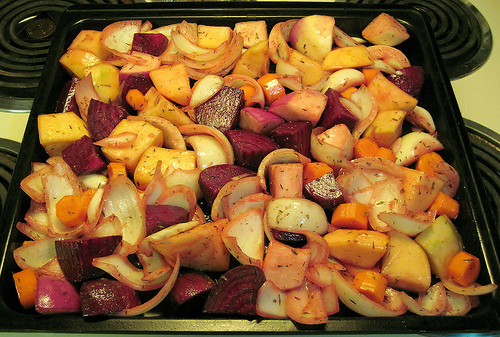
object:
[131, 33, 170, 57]
beet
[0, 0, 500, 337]
pan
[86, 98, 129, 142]
beet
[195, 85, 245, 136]
beet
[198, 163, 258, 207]
beet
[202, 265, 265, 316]
beet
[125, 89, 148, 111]
carrot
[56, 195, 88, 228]
carrot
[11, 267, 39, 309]
carrot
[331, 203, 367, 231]
carrot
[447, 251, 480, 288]
carrot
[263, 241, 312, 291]
onion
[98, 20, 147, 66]
onion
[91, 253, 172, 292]
onion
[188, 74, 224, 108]
onion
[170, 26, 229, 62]
onion